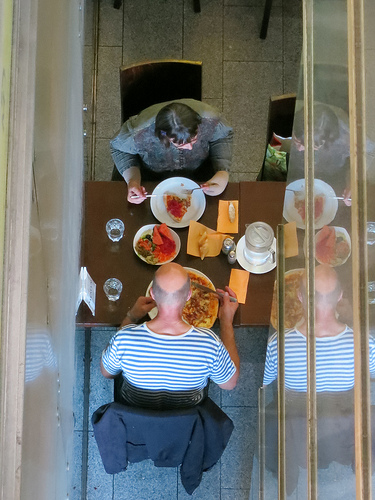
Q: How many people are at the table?
A: Two.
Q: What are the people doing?
A: Eating.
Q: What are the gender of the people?
A: Men.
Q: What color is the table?
A: Brown.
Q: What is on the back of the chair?
A: Jacket.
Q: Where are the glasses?
A: Table.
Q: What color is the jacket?
A: Blue.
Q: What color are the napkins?
A: Orange.